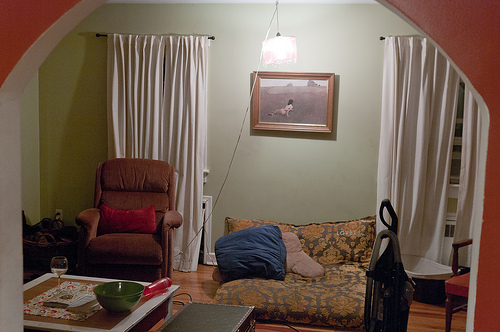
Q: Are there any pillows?
A: Yes, there is a pillow.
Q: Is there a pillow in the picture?
A: Yes, there is a pillow.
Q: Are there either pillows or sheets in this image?
A: Yes, there is a pillow.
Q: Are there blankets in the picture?
A: No, there are no blankets.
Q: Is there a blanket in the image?
A: No, there are no blankets.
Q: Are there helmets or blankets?
A: No, there are no blankets or helmets.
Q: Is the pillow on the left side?
A: Yes, the pillow is on the left of the image.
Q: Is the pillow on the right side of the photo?
A: No, the pillow is on the left of the image.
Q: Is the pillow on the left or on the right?
A: The pillow is on the left of the image.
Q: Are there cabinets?
A: No, there are no cabinets.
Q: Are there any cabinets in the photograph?
A: No, there are no cabinets.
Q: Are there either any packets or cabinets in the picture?
A: No, there are no cabinets or packets.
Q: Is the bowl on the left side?
A: Yes, the bowl is on the left of the image.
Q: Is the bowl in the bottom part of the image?
A: Yes, the bowl is in the bottom of the image.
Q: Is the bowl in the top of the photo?
A: No, the bowl is in the bottom of the image.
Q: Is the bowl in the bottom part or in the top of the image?
A: The bowl is in the bottom of the image.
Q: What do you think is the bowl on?
A: The bowl is on the table.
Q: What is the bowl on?
A: The bowl is on the table.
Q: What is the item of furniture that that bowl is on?
A: The piece of furniture is a table.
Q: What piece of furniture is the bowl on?
A: The bowl is on the table.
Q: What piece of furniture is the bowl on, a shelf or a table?
A: The bowl is on a table.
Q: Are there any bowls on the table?
A: Yes, there is a bowl on the table.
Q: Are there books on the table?
A: No, there is a bowl on the table.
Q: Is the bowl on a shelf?
A: No, the bowl is on a table.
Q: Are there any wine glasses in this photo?
A: Yes, there is a wine glass.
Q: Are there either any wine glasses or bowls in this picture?
A: Yes, there is a wine glass.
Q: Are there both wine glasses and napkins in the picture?
A: No, there is a wine glass but no napkins.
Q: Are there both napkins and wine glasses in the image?
A: No, there is a wine glass but no napkins.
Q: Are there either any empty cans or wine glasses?
A: Yes, there is an empty wine glass.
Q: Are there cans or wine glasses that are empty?
A: Yes, the wine glass is empty.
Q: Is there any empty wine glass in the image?
A: Yes, there is an empty wine glass.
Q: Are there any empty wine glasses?
A: Yes, there is an empty wine glass.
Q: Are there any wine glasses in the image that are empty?
A: Yes, there is a wine glass that is empty.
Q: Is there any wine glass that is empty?
A: Yes, there is a wine glass that is empty.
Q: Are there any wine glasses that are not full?
A: Yes, there is a empty wine glass.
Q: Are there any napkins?
A: No, there are no napkins.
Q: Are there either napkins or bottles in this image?
A: No, there are no napkins or bottles.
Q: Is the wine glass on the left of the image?
A: Yes, the wine glass is on the left of the image.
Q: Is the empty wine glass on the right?
A: No, the wine glass is on the left of the image.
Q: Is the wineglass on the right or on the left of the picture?
A: The wineglass is on the left of the image.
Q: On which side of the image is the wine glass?
A: The wine glass is on the left of the image.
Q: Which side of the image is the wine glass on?
A: The wine glass is on the left of the image.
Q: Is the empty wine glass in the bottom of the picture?
A: Yes, the wineglass is in the bottom of the image.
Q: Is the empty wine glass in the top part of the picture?
A: No, the wine glass is in the bottom of the image.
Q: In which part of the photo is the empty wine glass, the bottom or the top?
A: The wine glass is in the bottom of the image.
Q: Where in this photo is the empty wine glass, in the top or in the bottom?
A: The wine glass is in the bottom of the image.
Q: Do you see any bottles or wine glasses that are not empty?
A: No, there is a wine glass but it is empty.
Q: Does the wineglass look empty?
A: Yes, the wineglass is empty.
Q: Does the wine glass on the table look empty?
A: Yes, the wine glass is empty.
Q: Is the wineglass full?
A: No, the wineglass is empty.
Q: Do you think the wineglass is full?
A: No, the wineglass is empty.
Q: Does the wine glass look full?
A: No, the wine glass is empty.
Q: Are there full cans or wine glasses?
A: No, there is a wine glass but it is empty.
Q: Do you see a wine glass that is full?
A: No, there is a wine glass but it is empty.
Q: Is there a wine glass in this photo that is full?
A: No, there is a wine glass but it is empty.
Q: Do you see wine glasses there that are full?
A: No, there is a wine glass but it is empty.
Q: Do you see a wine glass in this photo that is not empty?
A: No, there is a wine glass but it is empty.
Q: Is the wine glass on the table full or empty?
A: The wineglass is empty.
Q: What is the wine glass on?
A: The wine glass is on the table.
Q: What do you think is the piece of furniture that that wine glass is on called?
A: The piece of furniture is a table.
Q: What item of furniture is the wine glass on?
A: The wine glass is on the table.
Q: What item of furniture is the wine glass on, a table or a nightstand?
A: The wine glass is on a table.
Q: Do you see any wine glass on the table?
A: Yes, there is a wine glass on the table.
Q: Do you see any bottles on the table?
A: No, there is a wine glass on the table.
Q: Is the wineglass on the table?
A: Yes, the wineglass is on the table.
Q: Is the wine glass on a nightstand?
A: No, the wine glass is on the table.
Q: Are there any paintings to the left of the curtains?
A: No, the painting is to the right of the curtains.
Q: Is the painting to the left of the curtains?
A: No, the painting is to the right of the curtains.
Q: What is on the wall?
A: The painting is on the wall.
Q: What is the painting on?
A: The painting is on the wall.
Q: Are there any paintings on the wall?
A: Yes, there is a painting on the wall.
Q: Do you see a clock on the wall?
A: No, there is a painting on the wall.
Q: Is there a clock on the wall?
A: No, there is a painting on the wall.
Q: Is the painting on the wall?
A: Yes, the painting is on the wall.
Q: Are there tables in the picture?
A: Yes, there is a table.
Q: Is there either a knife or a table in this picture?
A: Yes, there is a table.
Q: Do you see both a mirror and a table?
A: No, there is a table but no mirrors.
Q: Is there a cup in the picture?
A: No, there are no cups.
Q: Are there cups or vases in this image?
A: No, there are no cups or vases.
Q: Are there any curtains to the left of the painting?
A: Yes, there are curtains to the left of the painting.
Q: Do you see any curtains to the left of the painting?
A: Yes, there are curtains to the left of the painting.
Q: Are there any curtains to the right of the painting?
A: No, the curtains are to the left of the painting.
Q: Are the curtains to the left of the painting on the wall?
A: Yes, the curtains are to the left of the painting.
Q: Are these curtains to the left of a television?
A: No, the curtains are to the left of the painting.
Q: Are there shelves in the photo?
A: No, there are no shelves.